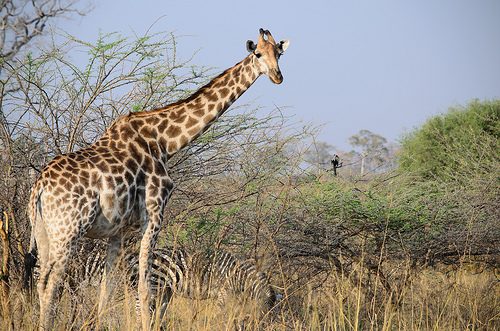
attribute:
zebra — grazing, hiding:
[131, 232, 289, 327]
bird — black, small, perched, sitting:
[327, 150, 345, 178]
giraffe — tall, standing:
[30, 35, 300, 326]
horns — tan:
[255, 21, 277, 51]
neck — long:
[155, 58, 246, 160]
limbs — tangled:
[281, 188, 459, 274]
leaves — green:
[439, 104, 496, 138]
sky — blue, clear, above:
[299, 2, 496, 96]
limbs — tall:
[0, 1, 186, 167]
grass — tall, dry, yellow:
[12, 314, 473, 330]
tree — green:
[346, 126, 389, 180]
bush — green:
[401, 82, 498, 180]